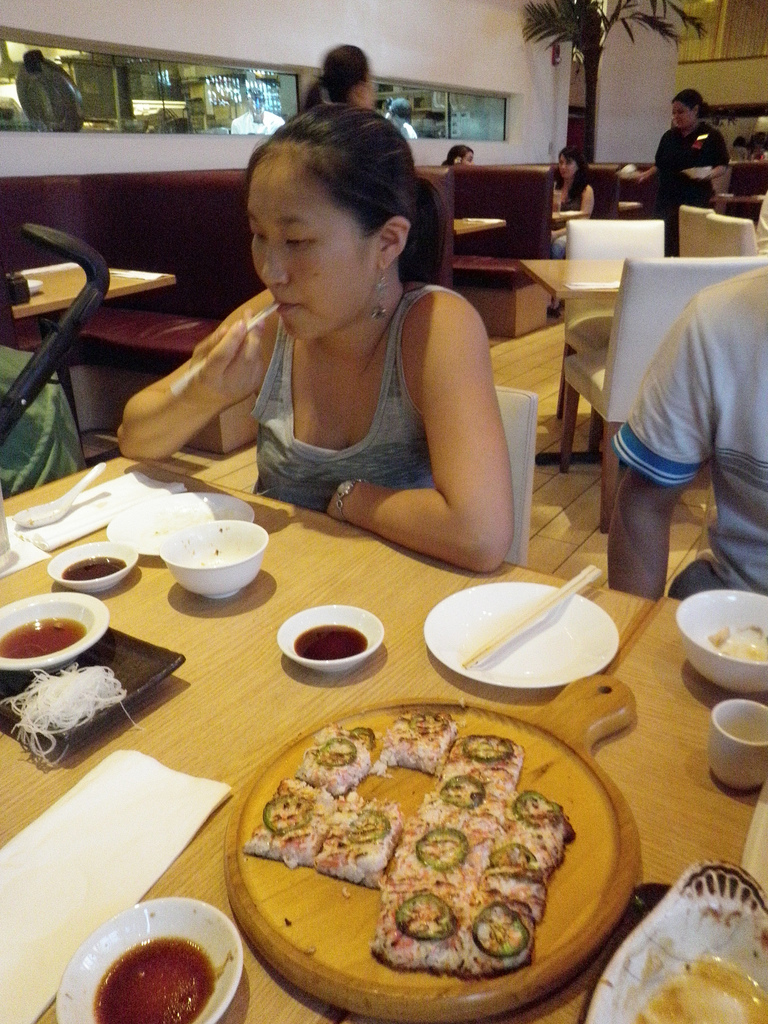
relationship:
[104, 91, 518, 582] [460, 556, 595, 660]
woman using chopstick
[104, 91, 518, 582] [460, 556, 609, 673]
woman using chopstick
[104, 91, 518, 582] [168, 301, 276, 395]
woman using pair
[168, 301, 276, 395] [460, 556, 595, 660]
pair of chopstick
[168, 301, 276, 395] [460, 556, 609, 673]
pair of chopstick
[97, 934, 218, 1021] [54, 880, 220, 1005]
red sauce in bowl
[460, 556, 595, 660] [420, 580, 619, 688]
chopstick on plate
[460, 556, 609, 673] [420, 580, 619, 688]
chopstick on plate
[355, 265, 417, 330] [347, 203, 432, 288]
earring in ear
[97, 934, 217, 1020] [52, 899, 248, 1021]
red sauce in bowl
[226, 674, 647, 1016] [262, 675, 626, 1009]
board holding food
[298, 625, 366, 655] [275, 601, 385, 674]
sauce in bowl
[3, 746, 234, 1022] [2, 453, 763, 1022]
napkin on table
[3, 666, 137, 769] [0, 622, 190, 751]
noodle on tray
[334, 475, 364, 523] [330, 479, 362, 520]
watch on wrist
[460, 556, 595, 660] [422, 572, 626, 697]
chopstick on plate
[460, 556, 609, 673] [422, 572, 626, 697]
chopstick on plate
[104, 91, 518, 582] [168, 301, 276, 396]
woman eating with pair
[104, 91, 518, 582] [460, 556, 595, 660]
woman eating with chopstick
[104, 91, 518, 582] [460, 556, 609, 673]
woman eating with chopstick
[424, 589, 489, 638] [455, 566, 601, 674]
white plate with set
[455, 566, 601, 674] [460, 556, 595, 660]
set of chopstick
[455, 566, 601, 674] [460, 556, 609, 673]
set of chopstick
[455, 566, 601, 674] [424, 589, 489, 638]
set on top of white plate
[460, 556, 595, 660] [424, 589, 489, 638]
chopstick on top of white plate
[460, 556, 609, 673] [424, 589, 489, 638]
chopstick on top of white plate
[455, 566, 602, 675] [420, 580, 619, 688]
set resting on plate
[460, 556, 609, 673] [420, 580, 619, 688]
chopstick resting on plate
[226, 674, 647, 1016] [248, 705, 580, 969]
board with food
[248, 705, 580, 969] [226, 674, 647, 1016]
food on top of board